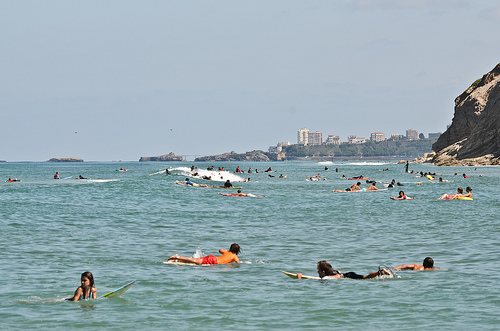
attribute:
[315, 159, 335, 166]
wave — white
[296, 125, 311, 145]
building — in background, large, above coastline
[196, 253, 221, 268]
swim trunks — red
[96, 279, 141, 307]
surfboard — blue, green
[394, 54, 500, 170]
cliff — rock, rocky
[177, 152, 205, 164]
bridge — faint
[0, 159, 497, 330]
ocean — full of people, blue, calm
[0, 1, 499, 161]
sky — gray, blue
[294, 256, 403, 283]
guy — wearing black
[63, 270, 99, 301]
girl — looking, surfing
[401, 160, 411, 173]
person — standing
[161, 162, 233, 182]
people — on wave crest, riding wave, paddling, swimming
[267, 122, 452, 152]
city — in distance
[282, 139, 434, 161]
trees — growing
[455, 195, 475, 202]
inner tube — yellow